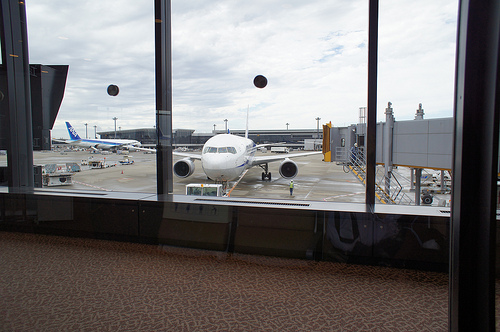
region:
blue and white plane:
[54, 120, 148, 155]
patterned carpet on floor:
[99, 265, 293, 325]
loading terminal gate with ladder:
[319, 111, 459, 203]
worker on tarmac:
[287, 178, 298, 197]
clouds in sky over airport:
[285, 12, 356, 92]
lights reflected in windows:
[7, 49, 54, 77]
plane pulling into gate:
[123, 133, 321, 193]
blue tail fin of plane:
[64, 117, 82, 142]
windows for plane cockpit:
[199, 143, 241, 155]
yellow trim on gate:
[319, 121, 338, 165]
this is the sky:
[66, 16, 99, 33]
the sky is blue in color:
[233, 1, 250, 13]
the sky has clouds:
[182, 17, 284, 47]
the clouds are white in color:
[221, 3, 300, 44]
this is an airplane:
[57, 118, 329, 183]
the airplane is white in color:
[209, 155, 226, 164]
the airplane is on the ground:
[109, 127, 336, 189]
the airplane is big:
[63, 82, 333, 188]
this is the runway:
[116, 165, 146, 182]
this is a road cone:
[112, 166, 127, 176]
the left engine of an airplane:
[280, 157, 300, 178]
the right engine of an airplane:
[172, 158, 188, 183]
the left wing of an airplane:
[254, 148, 320, 162]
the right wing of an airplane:
[126, 141, 202, 163]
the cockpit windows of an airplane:
[202, 146, 237, 154]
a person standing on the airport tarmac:
[282, 179, 302, 195]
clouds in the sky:
[198, 9, 320, 57]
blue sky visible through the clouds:
[322, 43, 349, 66]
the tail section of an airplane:
[63, 120, 81, 146]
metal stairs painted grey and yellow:
[346, 150, 403, 202]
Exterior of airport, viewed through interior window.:
[5, 2, 495, 327]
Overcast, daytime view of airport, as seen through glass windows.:
[8, 3, 495, 330]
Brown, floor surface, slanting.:
[16, 240, 343, 325]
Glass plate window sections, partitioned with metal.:
[1, 6, 458, 217]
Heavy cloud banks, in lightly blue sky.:
[204, 21, 333, 81]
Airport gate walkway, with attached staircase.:
[333, 120, 470, 217]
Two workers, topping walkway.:
[385, 98, 429, 125]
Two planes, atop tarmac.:
[61, 111, 306, 186]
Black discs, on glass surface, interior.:
[104, 81, 311, 193]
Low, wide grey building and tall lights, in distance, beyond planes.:
[128, 115, 340, 151]